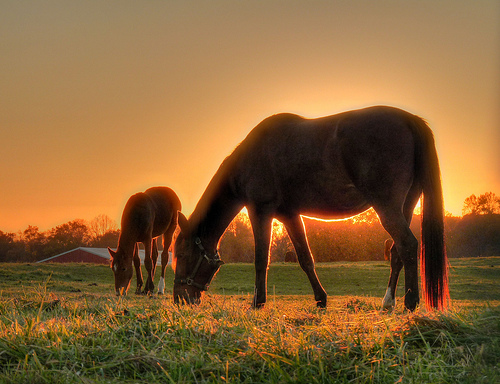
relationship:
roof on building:
[39, 251, 175, 262] [41, 250, 116, 260]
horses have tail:
[101, 100, 453, 306] [410, 124, 448, 312]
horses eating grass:
[101, 100, 453, 306] [1, 274, 494, 377]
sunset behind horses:
[418, 89, 496, 208] [101, 100, 453, 306]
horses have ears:
[101, 100, 453, 306] [177, 211, 193, 240]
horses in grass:
[101, 100, 453, 306] [1, 274, 494, 377]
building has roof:
[41, 250, 116, 260] [39, 251, 175, 262]